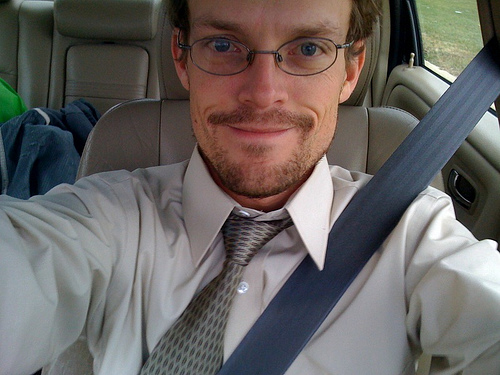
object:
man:
[0, 0, 500, 374]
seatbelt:
[217, 36, 499, 374]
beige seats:
[0, 2, 185, 125]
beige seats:
[73, 4, 427, 195]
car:
[0, 1, 498, 372]